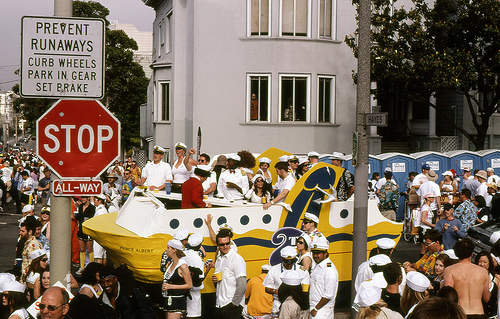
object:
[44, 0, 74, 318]
pole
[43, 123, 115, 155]
stop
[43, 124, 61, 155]
s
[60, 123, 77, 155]
t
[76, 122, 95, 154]
o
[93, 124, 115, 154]
p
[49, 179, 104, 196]
sign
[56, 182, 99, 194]
all-way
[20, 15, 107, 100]
sign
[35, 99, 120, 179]
stop sign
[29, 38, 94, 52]
word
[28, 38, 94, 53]
runaways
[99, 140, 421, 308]
parade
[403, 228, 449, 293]
people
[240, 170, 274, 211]
people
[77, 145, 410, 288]
float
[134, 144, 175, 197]
captain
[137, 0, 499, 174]
building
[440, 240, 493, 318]
man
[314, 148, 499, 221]
outhouses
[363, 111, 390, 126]
signage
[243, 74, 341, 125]
windows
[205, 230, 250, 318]
person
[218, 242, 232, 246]
glasses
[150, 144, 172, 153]
hat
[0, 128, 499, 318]
crowd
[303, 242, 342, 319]
person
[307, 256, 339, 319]
shirt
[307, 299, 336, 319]
pants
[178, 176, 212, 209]
shirt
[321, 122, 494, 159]
side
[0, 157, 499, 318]
road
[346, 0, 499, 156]
tree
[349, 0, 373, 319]
pole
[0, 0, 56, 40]
sky